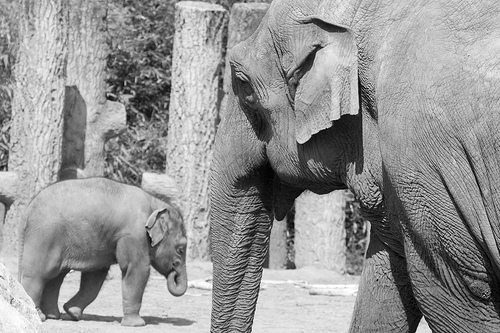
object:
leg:
[68, 269, 107, 303]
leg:
[38, 266, 70, 309]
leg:
[19, 254, 44, 314]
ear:
[277, 15, 360, 144]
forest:
[97, 0, 173, 186]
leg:
[113, 228, 150, 319]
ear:
[145, 207, 173, 247]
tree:
[5, 0, 66, 195]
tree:
[60, 1, 106, 180]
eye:
[237, 75, 254, 99]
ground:
[0, 262, 500, 333]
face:
[208, 0, 358, 222]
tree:
[162, 0, 227, 264]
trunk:
[208, 165, 273, 333]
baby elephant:
[18, 175, 188, 327]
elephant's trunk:
[205, 102, 273, 333]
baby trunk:
[166, 261, 189, 296]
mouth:
[165, 262, 179, 277]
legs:
[17, 264, 59, 323]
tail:
[13, 219, 29, 290]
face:
[146, 227, 189, 277]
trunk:
[164, 261, 189, 296]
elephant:
[206, 0, 499, 333]